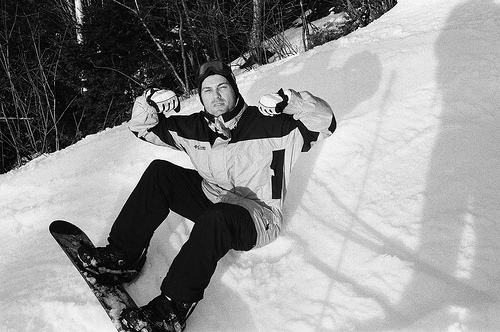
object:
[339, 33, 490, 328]
slope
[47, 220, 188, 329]
snowboarder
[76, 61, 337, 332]
man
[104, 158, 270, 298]
pants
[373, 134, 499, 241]
snow